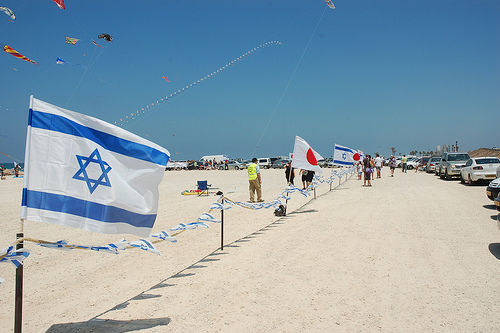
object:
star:
[72, 147, 113, 193]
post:
[221, 194, 224, 250]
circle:
[306, 148, 318, 166]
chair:
[197, 180, 211, 197]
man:
[362, 154, 372, 187]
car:
[460, 157, 499, 186]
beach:
[0, 167, 495, 332]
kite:
[65, 36, 80, 46]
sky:
[0, 0, 497, 162]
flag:
[13, 94, 170, 333]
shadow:
[45, 172, 358, 331]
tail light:
[473, 166, 484, 170]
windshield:
[448, 154, 471, 161]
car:
[435, 152, 471, 180]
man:
[247, 158, 264, 203]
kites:
[3, 44, 39, 69]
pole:
[14, 219, 23, 333]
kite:
[56, 57, 66, 64]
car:
[166, 159, 189, 171]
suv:
[166, 162, 189, 171]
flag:
[284, 135, 325, 217]